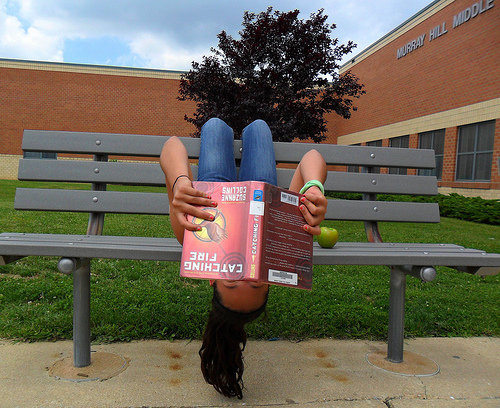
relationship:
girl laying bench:
[163, 118, 324, 398] [3, 130, 500, 269]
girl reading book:
[163, 118, 324, 398] [177, 179, 315, 290]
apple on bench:
[318, 224, 342, 250] [3, 130, 500, 269]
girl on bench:
[163, 118, 324, 398] [3, 130, 500, 269]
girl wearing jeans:
[163, 118, 324, 398] [199, 118, 276, 178]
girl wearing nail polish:
[163, 118, 324, 398] [298, 194, 314, 232]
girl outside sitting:
[163, 118, 324, 398] [156, 111, 327, 255]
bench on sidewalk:
[3, 130, 500, 269] [1, 338, 497, 404]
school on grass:
[328, 0, 498, 146] [3, 190, 500, 343]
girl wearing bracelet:
[163, 118, 324, 398] [296, 181, 327, 193]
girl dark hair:
[163, 118, 324, 398] [200, 285, 273, 401]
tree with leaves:
[178, 0, 362, 144] [347, 79, 350, 98]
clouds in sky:
[0, 5, 72, 58] [3, 0, 428, 57]